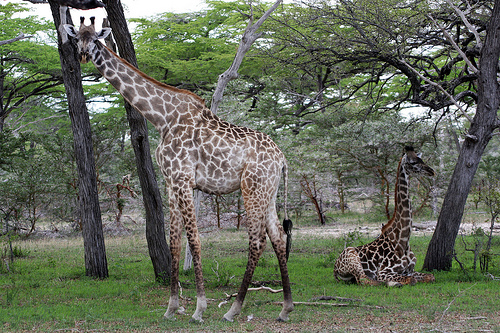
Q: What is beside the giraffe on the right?
A: A tall branch filled tree.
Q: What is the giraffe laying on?
A: A field of lush green grass.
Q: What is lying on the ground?
A: A giraffe with its head up.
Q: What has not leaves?
A: A large tree tilting to the right.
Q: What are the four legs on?
A: The standing giraffe.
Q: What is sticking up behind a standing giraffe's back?
A: Thin gray branch.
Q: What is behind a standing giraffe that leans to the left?
A: Two brown trees.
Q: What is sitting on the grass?
A: A giraffe.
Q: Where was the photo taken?
A: In the woods.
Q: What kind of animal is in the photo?
A: Giraffes.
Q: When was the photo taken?
A: During the day.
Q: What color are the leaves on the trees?
A: Green.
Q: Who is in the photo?
A: No one.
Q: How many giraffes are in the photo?
A: Two.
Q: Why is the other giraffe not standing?
A: It's resting.